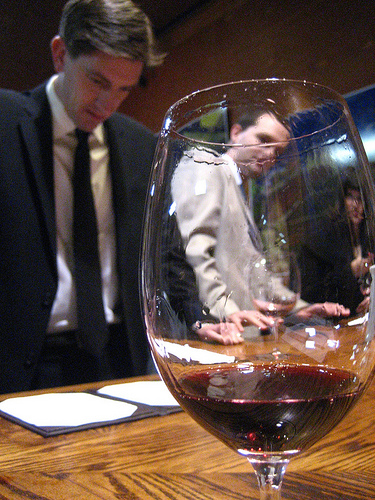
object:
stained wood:
[0, 325, 375, 500]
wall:
[115, 0, 374, 136]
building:
[0, 0, 375, 500]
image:
[177, 107, 229, 149]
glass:
[136, 77, 374, 500]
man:
[168, 103, 350, 331]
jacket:
[169, 144, 313, 319]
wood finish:
[0, 310, 375, 500]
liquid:
[166, 363, 364, 451]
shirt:
[43, 72, 124, 337]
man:
[0, 0, 243, 397]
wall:
[0, 0, 63, 94]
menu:
[0, 379, 183, 438]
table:
[0, 308, 375, 497]